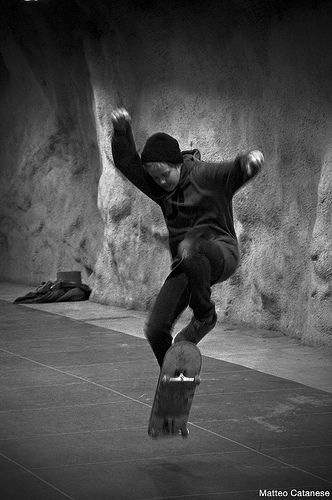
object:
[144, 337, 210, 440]
skateboard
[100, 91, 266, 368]
boy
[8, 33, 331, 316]
wall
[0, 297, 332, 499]
floor